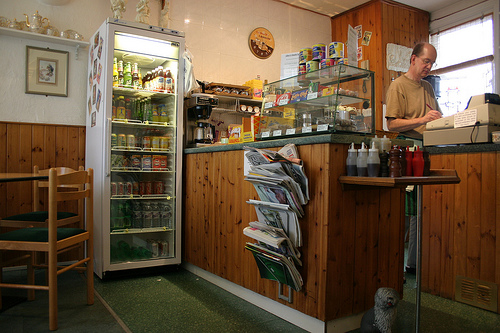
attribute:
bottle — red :
[408, 139, 426, 178]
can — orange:
[151, 151, 179, 178]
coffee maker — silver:
[182, 91, 217, 147]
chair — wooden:
[2, 166, 96, 331]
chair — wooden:
[0, 162, 85, 297]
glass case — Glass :
[261, 65, 381, 137]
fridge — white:
[89, 17, 183, 270]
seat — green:
[6, 221, 84, 246]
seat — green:
[8, 204, 72, 228]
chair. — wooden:
[15, 105, 133, 326]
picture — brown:
[11, 34, 85, 118]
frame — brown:
[19, 86, 70, 102]